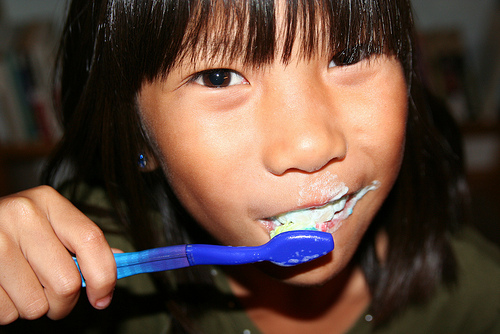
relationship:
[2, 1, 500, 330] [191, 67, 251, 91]
girl has an eye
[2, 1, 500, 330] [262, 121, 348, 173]
girl has a nose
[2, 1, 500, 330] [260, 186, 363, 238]
girl has a mouth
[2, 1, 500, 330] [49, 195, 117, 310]
girl has a finger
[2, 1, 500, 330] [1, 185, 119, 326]
girl has a hand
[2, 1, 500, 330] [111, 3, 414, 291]
girl has a head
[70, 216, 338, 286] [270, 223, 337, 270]
toothbrush has a head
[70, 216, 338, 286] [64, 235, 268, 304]
toothbrush has a handle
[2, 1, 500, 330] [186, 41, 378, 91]
girl has eyes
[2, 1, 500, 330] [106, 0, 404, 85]
girl has bangs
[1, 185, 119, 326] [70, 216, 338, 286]
hand holding toothbrush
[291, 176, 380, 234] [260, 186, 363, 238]
toothpaste around mouth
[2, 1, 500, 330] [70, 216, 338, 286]
girl holding toothbrush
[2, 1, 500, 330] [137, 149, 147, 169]
girl wearing earring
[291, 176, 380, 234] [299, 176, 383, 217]
toothpaste on girl's cheek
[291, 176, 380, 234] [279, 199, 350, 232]
toothpaste on girl's teeth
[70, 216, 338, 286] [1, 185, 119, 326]
toothbrush in hand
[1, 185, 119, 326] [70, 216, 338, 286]
fingers are around toothbrush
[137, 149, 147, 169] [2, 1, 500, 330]
earring on girl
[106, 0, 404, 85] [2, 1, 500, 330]
bangs are on girl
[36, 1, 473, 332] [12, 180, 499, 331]
hair on girl's shoulder